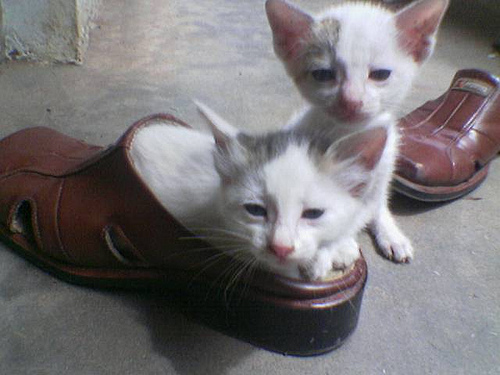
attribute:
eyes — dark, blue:
[310, 64, 397, 85]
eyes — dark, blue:
[230, 194, 329, 226]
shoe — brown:
[395, 65, 497, 203]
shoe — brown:
[5, 112, 367, 355]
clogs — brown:
[34, 92, 453, 370]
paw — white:
[377, 235, 414, 264]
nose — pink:
[269, 240, 294, 259]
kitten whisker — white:
[189, 219, 238, 245]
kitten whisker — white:
[197, 241, 227, 258]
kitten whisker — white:
[205, 258, 246, 270]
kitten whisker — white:
[316, 266, 341, 291]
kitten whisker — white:
[329, 257, 360, 283]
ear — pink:
[320, 112, 390, 207]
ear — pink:
[265, 3, 316, 53]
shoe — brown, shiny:
[7, 162, 152, 264]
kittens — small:
[151, 6, 419, 298]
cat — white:
[143, 101, 387, 293]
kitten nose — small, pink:
[267, 242, 297, 263]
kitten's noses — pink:
[335, 90, 370, 119]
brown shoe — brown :
[2, 104, 368, 357]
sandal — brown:
[14, 122, 364, 337]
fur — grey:
[219, 133, 315, 181]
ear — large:
[260, 5, 313, 55]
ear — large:
[393, 3, 443, 56]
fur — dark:
[295, 31, 338, 62]